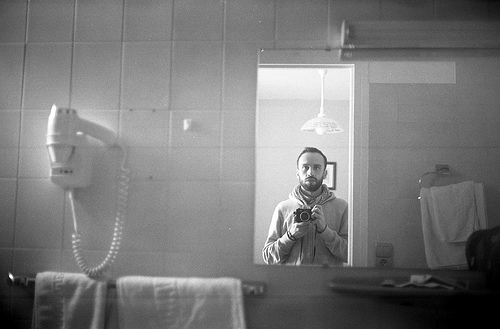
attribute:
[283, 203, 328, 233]
hands — mans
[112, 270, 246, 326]
towel — white 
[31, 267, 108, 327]
towel — white 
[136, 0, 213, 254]
wall — tiled 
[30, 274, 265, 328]
towel — folded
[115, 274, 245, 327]
towel — white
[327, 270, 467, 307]
shelf — small